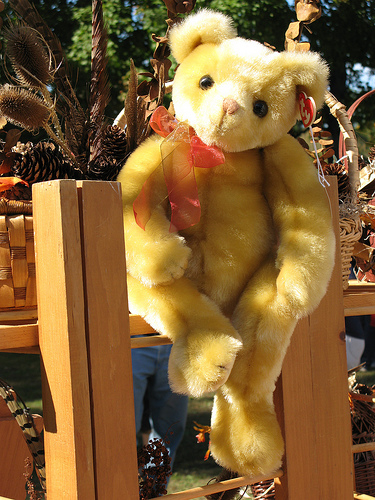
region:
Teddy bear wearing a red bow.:
[130, 19, 335, 223]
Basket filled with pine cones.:
[13, 134, 67, 183]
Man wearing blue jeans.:
[121, 336, 201, 488]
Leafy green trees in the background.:
[109, 6, 155, 62]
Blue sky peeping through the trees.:
[340, 50, 370, 99]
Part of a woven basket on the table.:
[0, 213, 34, 259]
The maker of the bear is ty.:
[281, 58, 343, 198]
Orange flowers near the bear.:
[187, 415, 210, 467]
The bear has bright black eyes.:
[182, 64, 278, 120]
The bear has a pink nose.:
[212, 86, 248, 125]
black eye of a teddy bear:
[250, 93, 271, 121]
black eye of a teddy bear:
[196, 71, 217, 92]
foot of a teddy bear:
[155, 311, 245, 403]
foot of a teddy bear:
[204, 408, 290, 485]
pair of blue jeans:
[122, 332, 197, 485]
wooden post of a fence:
[27, 165, 142, 499]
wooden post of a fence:
[270, 164, 358, 499]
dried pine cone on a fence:
[7, 140, 82, 196]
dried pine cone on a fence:
[87, 152, 125, 184]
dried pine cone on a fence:
[87, 119, 137, 160]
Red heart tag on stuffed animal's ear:
[298, 90, 317, 127]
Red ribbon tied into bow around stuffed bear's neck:
[131, 104, 225, 234]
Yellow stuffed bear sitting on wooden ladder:
[31, 8, 355, 499]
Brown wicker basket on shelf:
[0, 200, 36, 321]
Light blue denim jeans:
[131, 337, 188, 493]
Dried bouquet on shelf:
[1, 0, 198, 177]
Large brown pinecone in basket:
[10, 138, 83, 181]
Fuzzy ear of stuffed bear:
[167, 8, 236, 62]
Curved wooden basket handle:
[338, 88, 374, 170]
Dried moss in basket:
[336, 187, 362, 218]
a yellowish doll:
[114, 8, 346, 338]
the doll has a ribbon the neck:
[148, 82, 232, 189]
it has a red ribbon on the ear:
[263, 69, 348, 236]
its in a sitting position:
[23, 86, 372, 356]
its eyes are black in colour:
[237, 91, 275, 124]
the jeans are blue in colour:
[132, 360, 180, 438]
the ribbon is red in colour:
[145, 107, 196, 223]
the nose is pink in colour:
[205, 84, 236, 147]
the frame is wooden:
[33, 180, 141, 498]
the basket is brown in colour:
[0, 188, 35, 316]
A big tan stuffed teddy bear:
[100, 5, 352, 476]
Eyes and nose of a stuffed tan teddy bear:
[183, 57, 286, 140]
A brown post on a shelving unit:
[27, 178, 141, 487]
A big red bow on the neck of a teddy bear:
[131, 96, 223, 242]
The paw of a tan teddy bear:
[203, 404, 299, 484]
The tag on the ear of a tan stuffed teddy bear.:
[280, 69, 326, 191]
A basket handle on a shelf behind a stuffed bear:
[327, 104, 373, 213]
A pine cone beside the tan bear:
[3, 137, 72, 177]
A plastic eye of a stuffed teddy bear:
[185, 68, 225, 93]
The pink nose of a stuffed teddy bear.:
[215, 91, 240, 116]